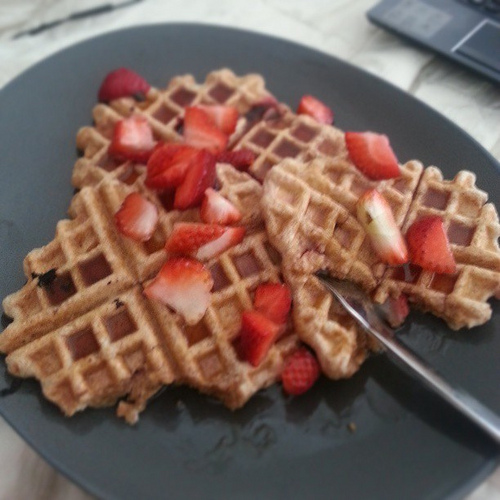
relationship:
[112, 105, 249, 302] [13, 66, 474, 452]
strawberries on waffles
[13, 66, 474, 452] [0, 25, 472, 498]
waffles on plate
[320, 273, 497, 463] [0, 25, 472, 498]
fork on plate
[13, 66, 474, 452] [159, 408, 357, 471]
waffles has syrup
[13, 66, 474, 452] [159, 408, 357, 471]
waffles have syrup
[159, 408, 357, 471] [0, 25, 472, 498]
syrup on plate